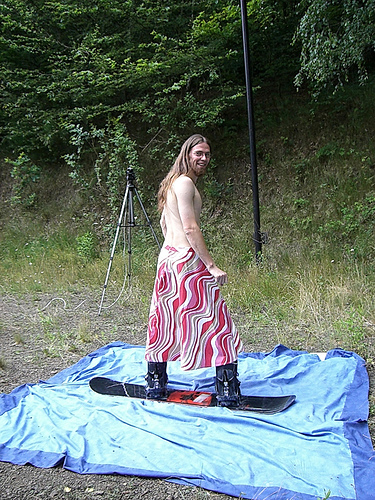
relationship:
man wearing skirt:
[146, 133, 242, 406] [149, 242, 243, 368]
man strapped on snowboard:
[146, 133, 242, 406] [89, 374, 296, 414]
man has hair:
[146, 133, 242, 406] [159, 130, 209, 212]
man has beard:
[146, 133, 242, 406] [189, 156, 205, 176]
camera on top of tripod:
[125, 166, 135, 181] [94, 187, 171, 323]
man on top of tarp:
[146, 133, 242, 406] [6, 335, 374, 498]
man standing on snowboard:
[146, 133, 242, 406] [89, 374, 296, 414]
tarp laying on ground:
[6, 335, 374, 498] [3, 262, 373, 499]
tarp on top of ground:
[6, 335, 374, 498] [3, 262, 373, 499]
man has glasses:
[146, 133, 242, 406] [192, 150, 213, 159]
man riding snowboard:
[146, 133, 242, 406] [89, 374, 296, 414]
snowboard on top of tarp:
[89, 374, 296, 414] [6, 335, 374, 498]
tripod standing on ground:
[94, 187, 171, 323] [3, 262, 373, 499]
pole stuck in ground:
[237, 2, 267, 267] [3, 262, 373, 499]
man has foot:
[146, 133, 242, 406] [215, 362, 238, 402]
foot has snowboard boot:
[215, 362, 238, 402] [215, 361, 242, 409]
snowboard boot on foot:
[144, 361, 170, 397] [215, 362, 238, 402]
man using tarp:
[146, 133, 242, 406] [6, 335, 374, 498]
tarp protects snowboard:
[6, 335, 374, 498] [89, 374, 296, 414]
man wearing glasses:
[146, 133, 242, 406] [192, 150, 213, 159]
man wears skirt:
[146, 133, 242, 406] [149, 242, 243, 368]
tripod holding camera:
[94, 187, 171, 323] [125, 166, 135, 181]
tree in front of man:
[4, 4, 370, 169] [146, 133, 242, 406]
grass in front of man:
[3, 229, 369, 341] [146, 133, 242, 406]